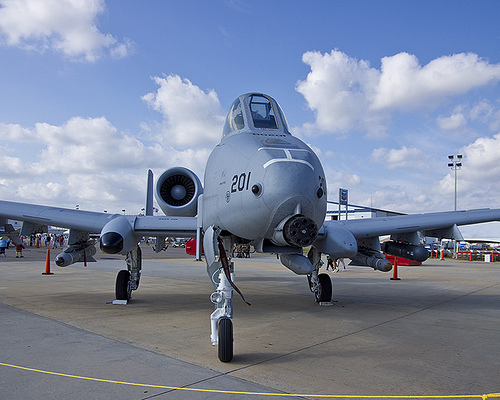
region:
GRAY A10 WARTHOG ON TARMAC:
[42, 95, 481, 398]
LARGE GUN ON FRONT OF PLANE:
[295, 209, 321, 259]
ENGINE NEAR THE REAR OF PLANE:
[152, 164, 198, 203]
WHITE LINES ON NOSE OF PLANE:
[270, 146, 296, 173]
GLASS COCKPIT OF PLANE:
[218, 79, 285, 130]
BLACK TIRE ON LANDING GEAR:
[209, 311, 236, 362]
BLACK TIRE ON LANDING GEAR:
[300, 274, 330, 302]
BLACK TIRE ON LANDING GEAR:
[112, 269, 151, 303]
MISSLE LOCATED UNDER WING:
[345, 241, 390, 282]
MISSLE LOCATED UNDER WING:
[57, 238, 104, 277]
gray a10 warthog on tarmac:
[12, 64, 478, 394]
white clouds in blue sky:
[288, 30, 448, 107]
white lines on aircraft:
[248, 136, 314, 168]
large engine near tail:
[157, 145, 198, 216]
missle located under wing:
[55, 244, 100, 269]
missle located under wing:
[357, 252, 394, 279]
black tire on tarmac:
[109, 264, 138, 292]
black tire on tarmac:
[213, 299, 233, 375]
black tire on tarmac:
[309, 271, 333, 301]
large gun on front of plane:
[284, 213, 319, 250]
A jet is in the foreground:
[0, 82, 498, 365]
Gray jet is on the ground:
[0, 77, 495, 367]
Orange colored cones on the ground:
[26, 243, 417, 296]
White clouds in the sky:
[0, 2, 497, 202]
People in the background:
[2, 223, 69, 263]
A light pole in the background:
[438, 147, 471, 240]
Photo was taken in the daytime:
[0, 1, 495, 396]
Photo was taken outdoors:
[2, 2, 497, 388]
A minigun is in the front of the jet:
[268, 204, 325, 264]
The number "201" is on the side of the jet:
[213, 166, 263, 199]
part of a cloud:
[315, 64, 342, 91]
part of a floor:
[331, 343, 356, 375]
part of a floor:
[338, 310, 348, 328]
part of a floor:
[193, 323, 213, 365]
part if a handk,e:
[221, 307, 230, 320]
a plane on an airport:
[0, 79, 498, 370]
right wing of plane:
[332, 188, 497, 248]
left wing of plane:
[4, 208, 204, 242]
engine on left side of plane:
[150, 161, 212, 221]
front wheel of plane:
[200, 301, 246, 367]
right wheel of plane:
[300, 265, 345, 311]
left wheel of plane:
[106, 262, 141, 307]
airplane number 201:
[220, 159, 260, 204]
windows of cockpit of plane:
[214, 76, 299, 150]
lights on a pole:
[437, 143, 471, 208]